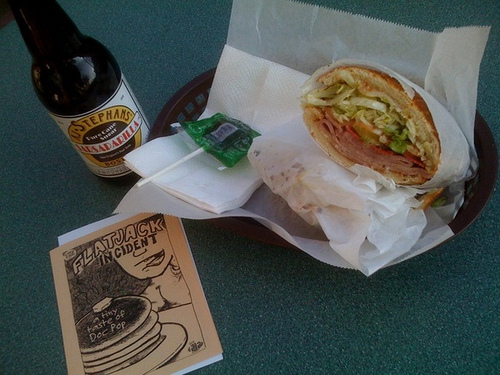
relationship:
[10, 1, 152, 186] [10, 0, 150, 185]
bottle of sasparilla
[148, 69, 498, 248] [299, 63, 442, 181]
tray has food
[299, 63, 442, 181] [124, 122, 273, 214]
food has napkins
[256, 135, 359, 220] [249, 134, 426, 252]
fries under paper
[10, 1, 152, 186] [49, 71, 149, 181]
bottle has label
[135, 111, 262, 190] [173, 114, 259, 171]
lollipop has wrapper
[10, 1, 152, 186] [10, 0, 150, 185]
bottle has sasparilla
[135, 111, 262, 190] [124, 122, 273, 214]
lollipop on napkins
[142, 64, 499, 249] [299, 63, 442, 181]
basket has food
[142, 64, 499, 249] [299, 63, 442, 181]
basket holds food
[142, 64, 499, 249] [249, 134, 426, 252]
basket has paper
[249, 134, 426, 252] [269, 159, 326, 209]
paper has grease spots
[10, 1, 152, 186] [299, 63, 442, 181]
beer next to food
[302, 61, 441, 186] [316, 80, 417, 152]
sandwhich has lettuce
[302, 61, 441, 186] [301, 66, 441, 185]
sandwhich has bread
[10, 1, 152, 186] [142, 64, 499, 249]
bottle next to basket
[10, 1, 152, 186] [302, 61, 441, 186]
bottle next to sandwhich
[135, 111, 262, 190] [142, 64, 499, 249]
lollipop in basket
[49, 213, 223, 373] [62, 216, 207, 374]
flyer has illustration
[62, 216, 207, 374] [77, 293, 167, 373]
illustration has pancakes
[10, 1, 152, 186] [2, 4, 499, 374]
bottle on table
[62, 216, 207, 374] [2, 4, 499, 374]
illustration on table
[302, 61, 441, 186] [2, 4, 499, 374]
sandwhich on table